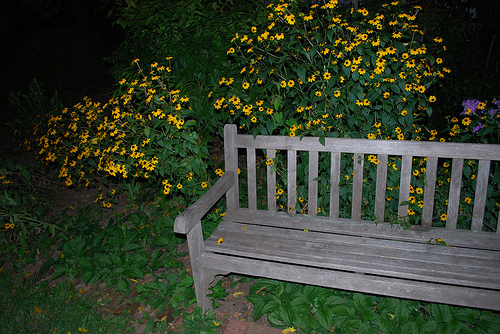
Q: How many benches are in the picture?
A: 1.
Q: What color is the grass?
A: Green.